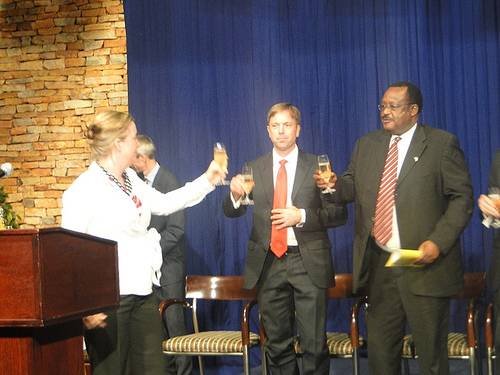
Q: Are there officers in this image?
A: No, there are no officers.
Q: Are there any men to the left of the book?
A: Yes, there is a man to the left of the book.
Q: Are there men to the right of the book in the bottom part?
A: No, the man is to the left of the book.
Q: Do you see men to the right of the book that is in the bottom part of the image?
A: No, the man is to the left of the book.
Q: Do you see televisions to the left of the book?
A: No, there is a man to the left of the book.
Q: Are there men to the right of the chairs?
A: Yes, there is a man to the right of the chairs.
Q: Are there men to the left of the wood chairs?
A: No, the man is to the right of the chairs.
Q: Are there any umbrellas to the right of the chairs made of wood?
A: No, there is a man to the right of the chairs.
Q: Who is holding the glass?
A: The man is holding the glass.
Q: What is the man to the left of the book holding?
A: The man is holding the glass.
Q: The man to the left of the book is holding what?
A: The man is holding the glass.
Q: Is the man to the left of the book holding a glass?
A: Yes, the man is holding a glass.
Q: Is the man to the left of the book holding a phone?
A: No, the man is holding a glass.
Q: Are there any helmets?
A: No, there are no helmets.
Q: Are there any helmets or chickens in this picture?
A: No, there are no helmets or chickens.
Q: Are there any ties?
A: Yes, there is a tie.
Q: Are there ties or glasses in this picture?
A: Yes, there is a tie.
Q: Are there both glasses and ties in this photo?
A: Yes, there are both a tie and glasses.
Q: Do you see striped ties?
A: Yes, there is a striped tie.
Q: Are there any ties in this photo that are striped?
A: Yes, there is a tie that is striped.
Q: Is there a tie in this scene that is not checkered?
A: Yes, there is a striped tie.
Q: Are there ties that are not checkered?
A: Yes, there is a striped tie.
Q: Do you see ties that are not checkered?
A: Yes, there is a striped tie.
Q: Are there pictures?
A: No, there are no pictures.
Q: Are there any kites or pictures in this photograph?
A: No, there are no pictures or kites.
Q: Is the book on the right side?
A: Yes, the book is on the right of the image.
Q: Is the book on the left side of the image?
A: No, the book is on the right of the image.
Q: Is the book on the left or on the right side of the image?
A: The book is on the right of the image.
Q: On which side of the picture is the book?
A: The book is on the right of the image.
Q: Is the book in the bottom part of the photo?
A: Yes, the book is in the bottom of the image.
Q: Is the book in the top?
A: No, the book is in the bottom of the image.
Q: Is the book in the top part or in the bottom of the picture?
A: The book is in the bottom of the image.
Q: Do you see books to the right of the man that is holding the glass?
A: Yes, there is a book to the right of the man.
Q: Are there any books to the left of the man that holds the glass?
A: No, the book is to the right of the man.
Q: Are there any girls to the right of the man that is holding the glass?
A: No, there is a book to the right of the man.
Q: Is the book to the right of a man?
A: Yes, the book is to the right of a man.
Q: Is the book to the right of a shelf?
A: No, the book is to the right of a man.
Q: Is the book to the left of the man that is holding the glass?
A: No, the book is to the right of the man.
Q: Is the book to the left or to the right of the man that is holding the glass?
A: The book is to the right of the man.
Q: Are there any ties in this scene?
A: Yes, there is a tie.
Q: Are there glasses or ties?
A: Yes, there is a tie.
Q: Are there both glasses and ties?
A: Yes, there are both a tie and glasses.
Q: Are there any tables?
A: No, there are no tables.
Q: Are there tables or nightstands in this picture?
A: No, there are no tables or nightstands.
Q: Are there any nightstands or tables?
A: No, there are no tables or nightstands.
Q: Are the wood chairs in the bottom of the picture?
A: Yes, the chairs are in the bottom of the image.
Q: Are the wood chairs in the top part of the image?
A: No, the chairs are in the bottom of the image.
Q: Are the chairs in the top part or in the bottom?
A: The chairs are in the bottom of the image.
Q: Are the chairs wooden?
A: Yes, the chairs are wooden.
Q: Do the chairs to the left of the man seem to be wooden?
A: Yes, the chairs are wooden.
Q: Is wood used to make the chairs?
A: Yes, the chairs are made of wood.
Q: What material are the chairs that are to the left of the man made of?
A: The chairs are made of wood.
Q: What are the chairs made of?
A: The chairs are made of wood.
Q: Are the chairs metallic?
A: No, the chairs are wooden.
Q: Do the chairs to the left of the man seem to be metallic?
A: No, the chairs are wooden.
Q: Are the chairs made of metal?
A: No, the chairs are made of wood.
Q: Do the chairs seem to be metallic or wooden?
A: The chairs are wooden.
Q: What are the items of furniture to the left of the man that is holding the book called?
A: The pieces of furniture are chairs.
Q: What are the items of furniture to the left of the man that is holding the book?
A: The pieces of furniture are chairs.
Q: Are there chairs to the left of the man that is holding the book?
A: Yes, there are chairs to the left of the man.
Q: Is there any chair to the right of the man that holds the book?
A: No, the chairs are to the left of the man.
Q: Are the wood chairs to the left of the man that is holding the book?
A: Yes, the chairs are to the left of the man.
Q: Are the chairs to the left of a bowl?
A: No, the chairs are to the left of the man.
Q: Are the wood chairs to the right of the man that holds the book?
A: No, the chairs are to the left of the man.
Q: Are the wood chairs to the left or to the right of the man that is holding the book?
A: The chairs are to the left of the man.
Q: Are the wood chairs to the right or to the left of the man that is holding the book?
A: The chairs are to the left of the man.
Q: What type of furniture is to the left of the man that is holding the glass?
A: The pieces of furniture are chairs.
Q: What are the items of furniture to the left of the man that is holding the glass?
A: The pieces of furniture are chairs.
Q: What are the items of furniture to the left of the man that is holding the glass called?
A: The pieces of furniture are chairs.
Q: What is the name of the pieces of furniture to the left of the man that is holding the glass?
A: The pieces of furniture are chairs.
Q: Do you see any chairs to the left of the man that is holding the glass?
A: Yes, there are chairs to the left of the man.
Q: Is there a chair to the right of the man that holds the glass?
A: No, the chairs are to the left of the man.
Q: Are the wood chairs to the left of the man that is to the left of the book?
A: Yes, the chairs are to the left of the man.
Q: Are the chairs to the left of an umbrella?
A: No, the chairs are to the left of the man.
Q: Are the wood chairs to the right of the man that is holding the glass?
A: No, the chairs are to the left of the man.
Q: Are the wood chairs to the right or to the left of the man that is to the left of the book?
A: The chairs are to the left of the man.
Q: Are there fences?
A: No, there are no fences.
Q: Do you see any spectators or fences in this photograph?
A: No, there are no fences or spectators.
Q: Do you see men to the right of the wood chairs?
A: Yes, there is a man to the right of the chairs.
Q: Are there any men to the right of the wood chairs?
A: Yes, there is a man to the right of the chairs.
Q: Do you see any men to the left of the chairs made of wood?
A: No, the man is to the right of the chairs.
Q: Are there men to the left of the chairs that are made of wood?
A: No, the man is to the right of the chairs.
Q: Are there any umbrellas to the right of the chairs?
A: No, there is a man to the right of the chairs.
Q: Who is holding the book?
A: The man is holding the book.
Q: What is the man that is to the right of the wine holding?
A: The man is holding the book.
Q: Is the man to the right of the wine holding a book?
A: Yes, the man is holding a book.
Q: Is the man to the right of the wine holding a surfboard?
A: No, the man is holding a book.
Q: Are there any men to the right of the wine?
A: Yes, there is a man to the right of the wine.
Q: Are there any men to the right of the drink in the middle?
A: Yes, there is a man to the right of the wine.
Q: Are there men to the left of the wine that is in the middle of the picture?
A: No, the man is to the right of the wine.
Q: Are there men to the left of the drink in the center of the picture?
A: No, the man is to the right of the wine.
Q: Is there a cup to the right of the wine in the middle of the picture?
A: No, there is a man to the right of the wine.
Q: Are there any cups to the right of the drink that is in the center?
A: No, there is a man to the right of the wine.